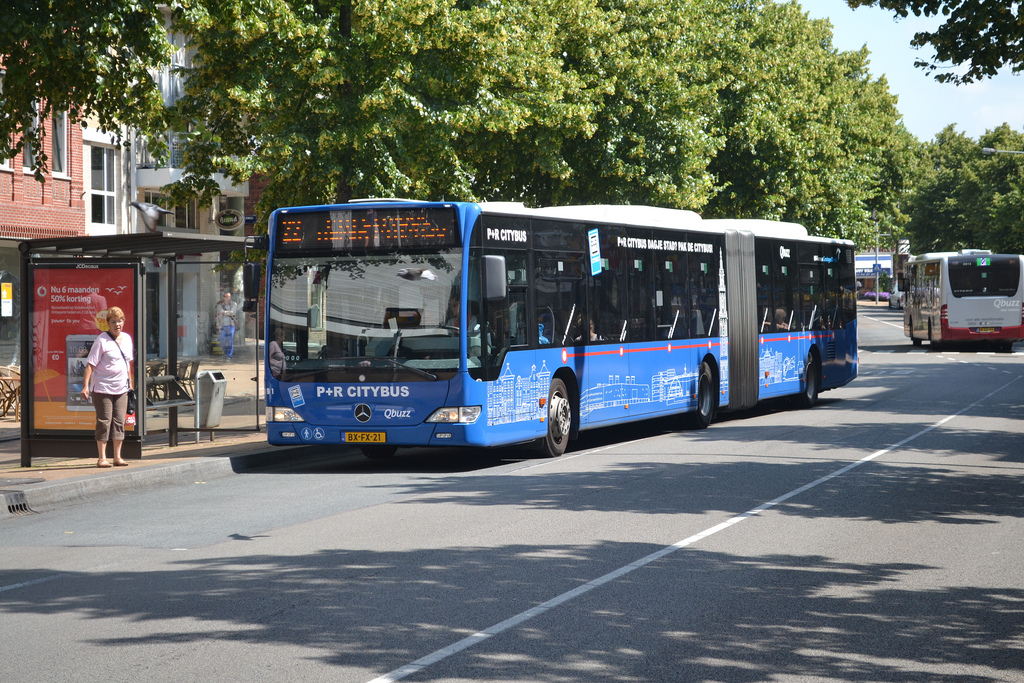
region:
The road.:
[0, 357, 1022, 672]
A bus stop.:
[14, 202, 240, 447]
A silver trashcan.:
[191, 364, 227, 432]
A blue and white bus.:
[172, 165, 932, 466]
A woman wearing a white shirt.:
[67, 313, 147, 438]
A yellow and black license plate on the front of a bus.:
[320, 426, 391, 446]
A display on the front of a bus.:
[270, 212, 458, 255]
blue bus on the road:
[220, 172, 876, 474]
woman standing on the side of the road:
[67, 307, 151, 476]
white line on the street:
[355, 357, 1023, 680]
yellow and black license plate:
[327, 418, 398, 448]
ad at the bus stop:
[23, 254, 142, 455]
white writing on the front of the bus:
[299, 371, 418, 409]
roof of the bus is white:
[396, 166, 845, 247]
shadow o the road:
[384, 447, 1023, 530]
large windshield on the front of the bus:
[266, 254, 462, 390]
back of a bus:
[937, 241, 1023, 359]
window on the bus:
[228, 252, 437, 355]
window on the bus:
[459, 256, 510, 326]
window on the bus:
[538, 246, 584, 346]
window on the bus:
[589, 266, 616, 343]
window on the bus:
[803, 250, 843, 321]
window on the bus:
[775, 275, 795, 323]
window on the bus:
[672, 268, 705, 335]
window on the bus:
[930, 262, 1003, 301]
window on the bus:
[904, 272, 939, 299]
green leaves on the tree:
[712, 126, 769, 216]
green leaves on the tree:
[797, 127, 830, 208]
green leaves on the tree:
[974, 161, 990, 220]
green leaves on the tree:
[873, 158, 1010, 270]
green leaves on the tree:
[397, 82, 475, 125]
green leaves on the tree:
[309, 59, 408, 158]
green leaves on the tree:
[179, 25, 320, 136]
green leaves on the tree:
[7, 3, 141, 112]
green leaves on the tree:
[955, 37, 1016, 77]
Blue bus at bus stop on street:
[263, 197, 855, 444]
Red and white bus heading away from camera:
[904, 250, 1021, 346]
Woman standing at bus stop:
[81, 307, 135, 462]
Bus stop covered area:
[19, 229, 263, 463]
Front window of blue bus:
[267, 261, 461, 373]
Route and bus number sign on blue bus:
[275, 213, 452, 253]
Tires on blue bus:
[542, 346, 838, 446]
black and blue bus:
[280, 165, 947, 463]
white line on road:
[813, 393, 900, 527]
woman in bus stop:
[64, 323, 137, 454]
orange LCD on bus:
[277, 189, 437, 329]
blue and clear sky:
[845, 25, 1020, 136]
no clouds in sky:
[819, 10, 1003, 115]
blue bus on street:
[255, 181, 866, 473]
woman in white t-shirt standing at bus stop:
[75, 301, 143, 472]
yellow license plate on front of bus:
[334, 423, 392, 452]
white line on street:
[357, 368, 1021, 681]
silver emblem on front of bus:
[343, 396, 379, 428]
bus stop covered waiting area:
[9, 220, 263, 486]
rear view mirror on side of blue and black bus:
[477, 242, 517, 307]